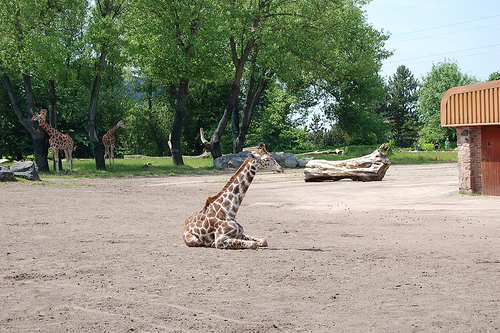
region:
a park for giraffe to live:
[7, 4, 492, 306]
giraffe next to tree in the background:
[30, 110, 77, 173]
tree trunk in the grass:
[170, 103, 187, 163]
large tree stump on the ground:
[304, 143, 394, 181]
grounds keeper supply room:
[441, 98, 498, 195]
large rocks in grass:
[216, 153, 243, 166]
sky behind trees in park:
[286, 98, 341, 131]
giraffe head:
[246, 145, 286, 174]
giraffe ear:
[250, 153, 256, 161]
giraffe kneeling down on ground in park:
[179, 144, 294, 247]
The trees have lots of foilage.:
[9, 7, 110, 89]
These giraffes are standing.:
[23, 98, 147, 180]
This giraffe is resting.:
[188, 138, 293, 279]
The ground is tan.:
[57, 250, 319, 330]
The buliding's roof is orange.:
[436, 69, 496, 128]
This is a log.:
[301, 148, 406, 182]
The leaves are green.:
[124, 41, 225, 83]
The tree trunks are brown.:
[173, 90, 255, 162]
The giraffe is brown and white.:
[186, 214, 242, 254]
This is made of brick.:
[454, 123, 481, 199]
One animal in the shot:
[136, 127, 305, 287]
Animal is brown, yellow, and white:
[143, 108, 293, 258]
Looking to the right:
[241, 133, 288, 185]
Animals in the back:
[21, 88, 148, 198]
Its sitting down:
[175, 133, 305, 260]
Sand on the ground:
[22, 205, 132, 300]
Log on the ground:
[300, 147, 420, 192]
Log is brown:
[305, 137, 390, 195]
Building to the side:
[405, 57, 495, 203]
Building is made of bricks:
[410, 63, 499, 189]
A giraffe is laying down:
[181, 145, 276, 254]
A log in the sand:
[302, 153, 387, 189]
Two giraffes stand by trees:
[33, 109, 126, 173]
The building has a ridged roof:
[444, 88, 496, 199]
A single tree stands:
[155, 4, 195, 165]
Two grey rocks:
[3, 162, 40, 185]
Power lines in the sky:
[411, 20, 499, 52]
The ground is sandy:
[11, 198, 126, 278]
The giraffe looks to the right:
[101, 110, 132, 167]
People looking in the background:
[428, 137, 453, 152]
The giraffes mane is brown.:
[195, 162, 249, 206]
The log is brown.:
[310, 148, 417, 188]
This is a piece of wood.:
[302, 152, 417, 188]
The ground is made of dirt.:
[295, 185, 480, 325]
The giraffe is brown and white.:
[30, 110, 91, 176]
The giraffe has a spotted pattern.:
[173, 180, 246, 242]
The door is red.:
[475, 125, 496, 185]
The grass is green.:
[120, 157, 190, 178]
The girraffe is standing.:
[85, 95, 141, 166]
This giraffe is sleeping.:
[176, 124, 315, 271]